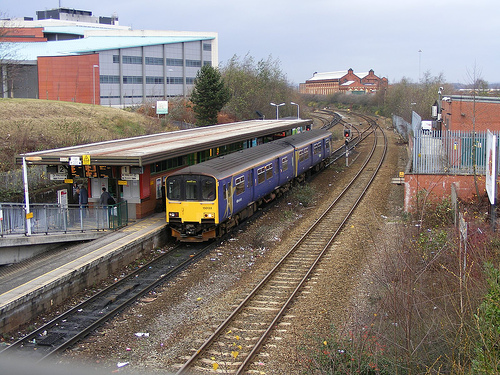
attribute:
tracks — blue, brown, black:
[13, 123, 392, 374]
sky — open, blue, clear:
[4, 5, 499, 80]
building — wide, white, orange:
[3, 11, 223, 110]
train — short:
[158, 115, 361, 238]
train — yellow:
[148, 122, 342, 253]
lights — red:
[340, 125, 350, 155]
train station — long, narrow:
[30, 108, 313, 232]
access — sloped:
[2, 196, 130, 285]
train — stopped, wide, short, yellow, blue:
[165, 128, 335, 248]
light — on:
[199, 210, 215, 220]